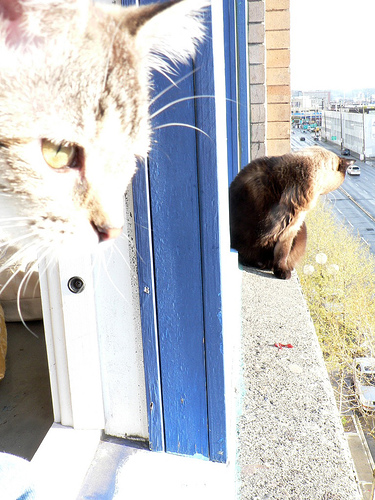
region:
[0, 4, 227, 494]
cat looking out open window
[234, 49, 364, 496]
cat seated on outdoor window ledge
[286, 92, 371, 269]
street between trees and buildings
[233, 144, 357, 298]
brown and tan cat looking down below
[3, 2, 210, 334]
light shining brightly on cat's face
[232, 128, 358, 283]
the cat is cream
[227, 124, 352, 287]
the cat is brown and cream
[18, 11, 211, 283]
the cat is striped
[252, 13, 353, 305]
the bricks are behind the cat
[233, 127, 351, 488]
the cat is on a ledge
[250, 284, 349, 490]
the ledge is stone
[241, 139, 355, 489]
the cat is on a stone ledge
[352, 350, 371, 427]
the car is white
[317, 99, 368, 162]
the building is white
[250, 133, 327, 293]
A cat sitting on the window pane.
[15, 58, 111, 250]
A cat looking out of the window.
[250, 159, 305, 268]
A brown cat sitting outside of the window.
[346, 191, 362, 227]
Yellow line in the road.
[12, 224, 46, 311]
The cat has long whiskers.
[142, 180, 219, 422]
The edge of the window is painted blue.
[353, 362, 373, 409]
A car parked on side of road.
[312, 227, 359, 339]
Trees below the building.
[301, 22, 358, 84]
The sky is clear.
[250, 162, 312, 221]
The cat is brown.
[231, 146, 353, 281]
A cat is on the ledge.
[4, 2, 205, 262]
A cat is looking out a window.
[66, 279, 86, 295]
A screw is visible on the window.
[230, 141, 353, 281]
The cat is looking down.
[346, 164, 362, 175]
Cars are on the road.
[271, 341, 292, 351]
A red object is on the ledge.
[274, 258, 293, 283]
The cat has dark paws.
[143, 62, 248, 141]
The cat has wiskers on the side of his face.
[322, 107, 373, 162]
A white building is in the background.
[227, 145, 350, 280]
The cat is tan colored.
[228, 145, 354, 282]
a cat out on the ledge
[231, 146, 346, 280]
a brown and tan cat on the ledge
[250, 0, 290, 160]
brick side of a wall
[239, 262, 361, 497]
a gray concrete ledge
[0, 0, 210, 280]
head of cat through a window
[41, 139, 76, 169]
large yellow cat's eye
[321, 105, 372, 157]
a large white building seen in the distance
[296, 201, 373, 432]
a group of yellow trees below the window ledge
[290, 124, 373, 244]
gray road seen the window ledge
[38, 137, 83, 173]
A yellow eye on a cat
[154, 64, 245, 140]
Whiskers on a cat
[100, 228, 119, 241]
A nose on a cat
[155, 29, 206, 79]
Fur in a cat's ear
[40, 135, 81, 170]
eye of a cat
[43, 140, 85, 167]
the eye is green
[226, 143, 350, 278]
the cat is standing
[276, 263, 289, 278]
paw of a cat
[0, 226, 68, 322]
whiskers of a cat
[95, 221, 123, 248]
nose of a cat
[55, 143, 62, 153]
the pupil is thin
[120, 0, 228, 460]
the paint is blue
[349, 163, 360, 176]
the car is white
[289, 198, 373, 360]
the grass is yellow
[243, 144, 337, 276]
a cat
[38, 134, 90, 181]
eye of the cat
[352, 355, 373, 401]
a car